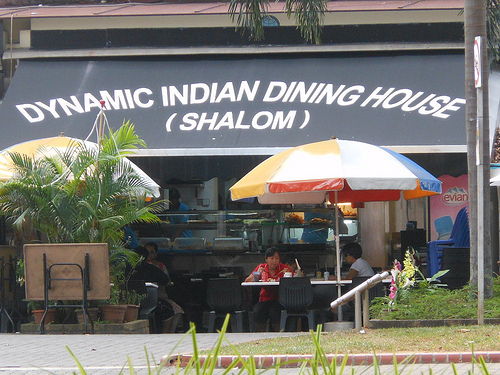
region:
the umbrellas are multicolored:
[222, 141, 445, 203]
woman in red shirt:
[248, 249, 296, 310]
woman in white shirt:
[338, 241, 375, 292]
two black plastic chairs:
[200, 273, 321, 324]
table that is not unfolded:
[18, 237, 113, 332]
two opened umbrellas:
[2, 137, 439, 211]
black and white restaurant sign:
[4, 71, 498, 134]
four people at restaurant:
[133, 238, 370, 291]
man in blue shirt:
[165, 192, 192, 245]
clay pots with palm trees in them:
[4, 156, 148, 324]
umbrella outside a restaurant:
[228, 133, 454, 205]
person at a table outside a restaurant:
[248, 247, 295, 328]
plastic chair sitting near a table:
[280, 274, 328, 336]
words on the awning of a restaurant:
[14, 77, 460, 144]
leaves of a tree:
[0, 125, 158, 240]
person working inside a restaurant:
[167, 187, 192, 243]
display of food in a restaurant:
[162, 209, 302, 246]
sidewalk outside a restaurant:
[2, 329, 242, 371]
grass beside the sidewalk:
[190, 329, 499, 369]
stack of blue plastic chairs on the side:
[428, 207, 468, 284]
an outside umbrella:
[186, 60, 443, 367]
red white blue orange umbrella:
[191, 78, 469, 253]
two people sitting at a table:
[211, 208, 422, 314]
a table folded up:
[4, 221, 171, 347]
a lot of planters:
[3, 268, 183, 368]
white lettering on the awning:
[19, 65, 498, 173]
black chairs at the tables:
[185, 232, 326, 355]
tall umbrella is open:
[204, 93, 489, 352]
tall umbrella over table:
[191, 94, 467, 351]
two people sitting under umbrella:
[219, 120, 471, 336]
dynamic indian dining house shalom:
[16, 82, 464, 129]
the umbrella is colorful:
[226, 140, 438, 208]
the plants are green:
[7, 122, 141, 246]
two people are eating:
[243, 239, 367, 283]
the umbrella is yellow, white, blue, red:
[231, 140, 443, 211]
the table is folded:
[21, 241, 111, 336]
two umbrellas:
[2, 140, 437, 199]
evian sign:
[428, 172, 470, 246]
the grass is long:
[0, 315, 498, 373]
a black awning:
[13, 56, 481, 151]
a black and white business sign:
[5, 55, 472, 154]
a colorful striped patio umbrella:
[226, 131, 444, 326]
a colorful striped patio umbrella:
[1, 129, 163, 220]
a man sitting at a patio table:
[241, 244, 303, 329]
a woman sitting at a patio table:
[337, 242, 375, 307]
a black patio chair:
[275, 273, 321, 338]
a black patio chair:
[194, 274, 246, 333]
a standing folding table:
[16, 240, 116, 337]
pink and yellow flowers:
[386, 248, 416, 317]